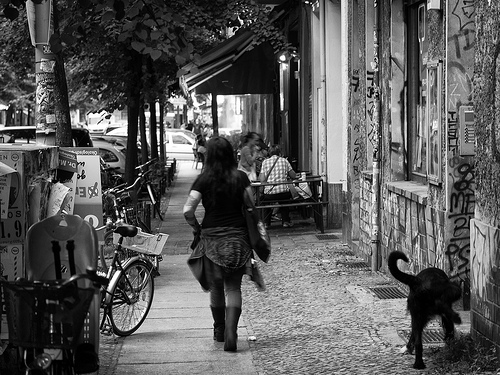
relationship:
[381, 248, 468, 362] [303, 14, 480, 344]
dog near wall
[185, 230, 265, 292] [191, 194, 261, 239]
sweater around waist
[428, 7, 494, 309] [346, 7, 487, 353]
graffiti painted on wall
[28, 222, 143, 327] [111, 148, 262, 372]
bikes parked on sidewalk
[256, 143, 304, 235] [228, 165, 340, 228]
person sitting at picnic table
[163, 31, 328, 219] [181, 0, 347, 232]
porch on building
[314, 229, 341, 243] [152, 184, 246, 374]
grate in sidewalk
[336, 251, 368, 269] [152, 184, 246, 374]
grate in sidewalk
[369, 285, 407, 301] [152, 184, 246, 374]
drainage in sidewalk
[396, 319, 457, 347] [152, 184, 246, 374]
grate in sidewalk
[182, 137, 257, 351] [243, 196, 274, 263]
woman carrying purse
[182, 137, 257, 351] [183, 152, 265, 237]
woman in a black shirt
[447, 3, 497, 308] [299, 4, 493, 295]
graffiti on building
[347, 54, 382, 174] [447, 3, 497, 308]
graffiti on graffiti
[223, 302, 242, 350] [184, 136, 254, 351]
boot on woman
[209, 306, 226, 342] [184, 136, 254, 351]
boot on woman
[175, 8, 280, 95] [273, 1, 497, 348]
awning of building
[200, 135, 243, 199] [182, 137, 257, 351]
hair on woman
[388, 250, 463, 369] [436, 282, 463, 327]
black animal lifting leg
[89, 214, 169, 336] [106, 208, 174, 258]
bike with basket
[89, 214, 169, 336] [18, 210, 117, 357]
bike with seat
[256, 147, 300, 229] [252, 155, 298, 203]
woman wearing shirt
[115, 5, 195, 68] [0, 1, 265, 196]
leaves hanging from trees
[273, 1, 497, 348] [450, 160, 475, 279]
building covered with graffiti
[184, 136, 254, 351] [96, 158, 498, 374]
woman walking down a sidewalk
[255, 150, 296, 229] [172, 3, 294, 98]
person under an awning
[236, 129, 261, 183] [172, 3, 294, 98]
person under an awning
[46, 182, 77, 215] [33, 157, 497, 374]
sign posted at side of sidewalk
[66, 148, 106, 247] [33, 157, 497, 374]
sign posted at side of sidewalk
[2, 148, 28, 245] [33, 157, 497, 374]
sign posted at side of sidewalk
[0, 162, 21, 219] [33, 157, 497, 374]
sign posted at side of sidewalk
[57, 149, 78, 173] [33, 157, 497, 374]
sign posted at side of sidewalk